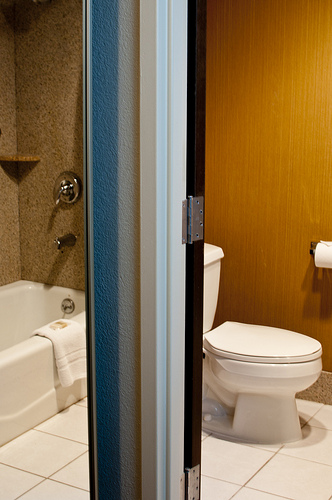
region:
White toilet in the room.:
[203, 238, 322, 447]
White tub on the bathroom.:
[0, 277, 86, 455]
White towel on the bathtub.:
[31, 316, 88, 388]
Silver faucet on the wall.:
[51, 232, 78, 253]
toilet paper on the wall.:
[305, 237, 330, 270]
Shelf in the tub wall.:
[0, 147, 37, 166]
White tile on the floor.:
[198, 397, 330, 498]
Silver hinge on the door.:
[184, 191, 203, 246]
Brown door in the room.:
[183, 1, 208, 498]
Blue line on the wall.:
[89, 1, 123, 499]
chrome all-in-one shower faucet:
[52, 171, 79, 211]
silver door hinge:
[181, 196, 203, 244]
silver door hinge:
[185, 464, 199, 498]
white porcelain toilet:
[203, 242, 322, 441]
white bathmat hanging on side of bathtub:
[33, 318, 87, 384]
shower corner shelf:
[0, 153, 41, 161]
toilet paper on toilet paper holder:
[308, 239, 330, 268]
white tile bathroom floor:
[2, 394, 330, 498]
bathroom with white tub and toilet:
[0, 0, 330, 497]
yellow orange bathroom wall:
[204, 2, 330, 406]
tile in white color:
[0, 392, 326, 492]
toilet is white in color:
[197, 318, 322, 437]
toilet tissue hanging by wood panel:
[195, 3, 329, 374]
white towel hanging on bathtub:
[0, 275, 84, 447]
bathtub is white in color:
[0, 275, 88, 449]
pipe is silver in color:
[43, 168, 79, 251]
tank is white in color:
[193, 234, 225, 335]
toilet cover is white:
[200, 316, 324, 367]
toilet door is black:
[180, 2, 204, 497]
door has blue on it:
[77, 3, 138, 497]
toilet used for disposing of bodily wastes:
[202, 241, 322, 440]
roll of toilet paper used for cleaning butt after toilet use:
[308, 239, 331, 269]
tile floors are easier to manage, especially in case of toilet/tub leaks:
[1, 391, 330, 499]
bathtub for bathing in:
[1, 278, 88, 446]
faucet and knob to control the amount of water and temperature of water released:
[50, 171, 80, 253]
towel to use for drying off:
[33, 317, 89, 381]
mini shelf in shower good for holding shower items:
[0, 142, 42, 171]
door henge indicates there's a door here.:
[184, 189, 206, 251]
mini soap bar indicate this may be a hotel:
[49, 318, 72, 329]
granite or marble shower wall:
[0, 0, 87, 295]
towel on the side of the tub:
[35, 306, 94, 395]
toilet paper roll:
[312, 228, 329, 272]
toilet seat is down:
[204, 296, 330, 382]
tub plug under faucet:
[55, 296, 81, 313]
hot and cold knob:
[50, 170, 82, 210]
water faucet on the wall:
[45, 224, 88, 259]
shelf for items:
[9, 124, 46, 173]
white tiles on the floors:
[11, 413, 316, 488]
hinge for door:
[186, 188, 217, 239]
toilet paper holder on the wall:
[304, 219, 327, 278]